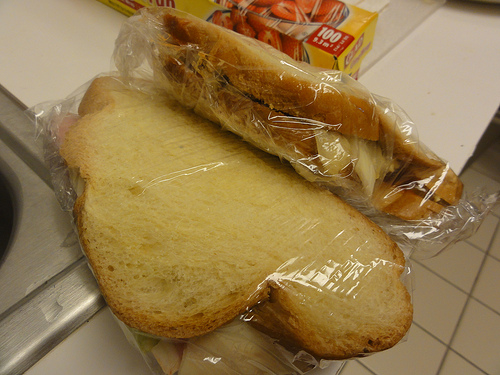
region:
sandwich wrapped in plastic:
[26, 6, 487, 363]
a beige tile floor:
[318, 136, 498, 373]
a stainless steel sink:
[0, 86, 122, 372]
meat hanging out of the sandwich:
[301, 115, 403, 193]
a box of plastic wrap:
[105, 0, 382, 83]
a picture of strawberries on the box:
[211, 9, 313, 61]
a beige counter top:
[2, 2, 494, 207]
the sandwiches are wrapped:
[30, 6, 491, 358]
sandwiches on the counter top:
[25, 9, 482, 349]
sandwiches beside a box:
[94, 0, 402, 102]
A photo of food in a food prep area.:
[1, 0, 499, 373]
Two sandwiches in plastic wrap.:
[55, 4, 498, 360]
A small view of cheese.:
[318, 129, 398, 188]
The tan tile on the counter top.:
[415, 252, 498, 373]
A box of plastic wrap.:
[288, 1, 458, 68]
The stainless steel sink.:
[1, 78, 93, 373]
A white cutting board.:
[381, 1, 498, 98]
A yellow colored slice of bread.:
[95, 213, 410, 360]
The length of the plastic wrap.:
[311, 18, 353, 58]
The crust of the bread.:
[308, 84, 368, 131]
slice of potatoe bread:
[63, 77, 407, 348]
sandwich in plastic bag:
[46, 96, 397, 350]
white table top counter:
[428, 79, 480, 121]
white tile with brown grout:
[428, 272, 479, 372]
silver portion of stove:
[25, 221, 83, 317]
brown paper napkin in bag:
[145, 338, 314, 362]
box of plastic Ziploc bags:
[222, 7, 385, 80]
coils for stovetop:
[1, 187, 10, 258]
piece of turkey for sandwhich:
[304, 125, 382, 177]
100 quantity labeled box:
[306, 22, 381, 69]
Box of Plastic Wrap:
[93, 2, 383, 79]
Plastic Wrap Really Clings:
[34, 8, 490, 362]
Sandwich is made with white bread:
[44, 3, 470, 362]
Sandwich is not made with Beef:
[47, 10, 471, 365]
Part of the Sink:
[2, 82, 104, 373]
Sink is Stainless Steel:
[4, 87, 111, 372]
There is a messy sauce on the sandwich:
[150, 7, 292, 142]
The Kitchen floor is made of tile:
[335, 117, 497, 372]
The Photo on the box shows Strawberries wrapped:
[195, 3, 390, 72]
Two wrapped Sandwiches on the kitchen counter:
[4, 6, 496, 373]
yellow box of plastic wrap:
[126, 8, 418, 64]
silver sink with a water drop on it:
[17, 157, 98, 359]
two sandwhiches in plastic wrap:
[102, 31, 455, 352]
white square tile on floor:
[400, 249, 498, 361]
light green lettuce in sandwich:
[279, 120, 415, 178]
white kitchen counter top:
[12, 6, 102, 108]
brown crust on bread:
[211, 67, 319, 132]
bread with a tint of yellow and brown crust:
[80, 163, 427, 329]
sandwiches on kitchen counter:
[45, 5, 457, 360]